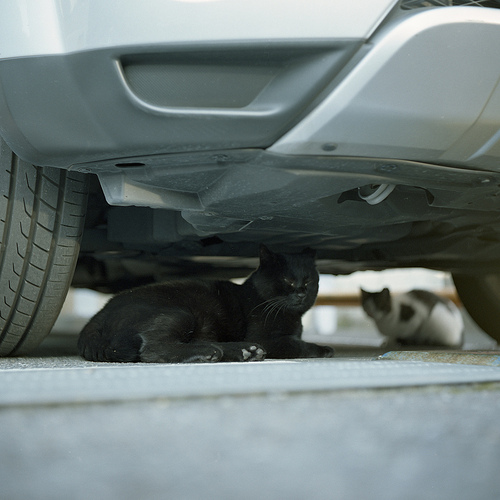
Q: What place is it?
A: It is a pavement.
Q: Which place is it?
A: It is a pavement.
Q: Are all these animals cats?
A: Yes, all the animals are cats.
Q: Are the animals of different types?
A: No, all the animals are cats.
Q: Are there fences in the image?
A: No, there are no fences.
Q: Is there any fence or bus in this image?
A: No, there are no fences or buses.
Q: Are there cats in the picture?
A: Yes, there is a cat.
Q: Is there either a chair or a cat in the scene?
A: Yes, there is a cat.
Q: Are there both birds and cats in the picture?
A: No, there is a cat but no birds.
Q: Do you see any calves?
A: No, there are no calves.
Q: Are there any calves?
A: No, there are no calves.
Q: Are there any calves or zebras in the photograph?
A: No, there are no calves or zebras.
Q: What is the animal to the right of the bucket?
A: The animal is a cat.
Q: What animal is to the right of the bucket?
A: The animal is a cat.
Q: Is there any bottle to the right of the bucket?
A: No, there is a cat to the right of the bucket.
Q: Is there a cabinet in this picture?
A: No, there are no cabinets.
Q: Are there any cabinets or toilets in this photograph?
A: No, there are no cabinets or toilets.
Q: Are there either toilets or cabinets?
A: No, there are no cabinets or toilets.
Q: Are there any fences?
A: No, there are no fences.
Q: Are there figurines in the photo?
A: No, there are no figurines.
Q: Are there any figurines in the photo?
A: No, there are no figurines.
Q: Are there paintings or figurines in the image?
A: No, there are no figurines or paintings.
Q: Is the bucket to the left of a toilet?
A: No, the bucket is to the left of the cat.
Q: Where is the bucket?
A: The bucket is on the ground.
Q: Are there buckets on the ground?
A: Yes, there is a bucket on the ground.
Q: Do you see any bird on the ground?
A: No, there is a bucket on the ground.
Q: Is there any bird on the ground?
A: No, there is a bucket on the ground.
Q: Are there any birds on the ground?
A: No, there is a bucket on the ground.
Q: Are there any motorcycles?
A: No, there are no motorcycles.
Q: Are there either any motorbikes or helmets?
A: No, there are no motorbikes or helmets.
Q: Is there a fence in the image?
A: No, there are no fences.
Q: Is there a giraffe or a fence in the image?
A: No, there are no fences or giraffes.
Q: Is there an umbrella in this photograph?
A: No, there are no umbrellas.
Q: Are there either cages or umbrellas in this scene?
A: No, there are no umbrellas or cages.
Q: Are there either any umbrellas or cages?
A: No, there are no umbrellas or cages.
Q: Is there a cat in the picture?
A: Yes, there are cats.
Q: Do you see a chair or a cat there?
A: Yes, there are cats.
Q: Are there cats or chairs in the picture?
A: Yes, there are cats.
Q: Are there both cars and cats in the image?
A: Yes, there are both cats and a car.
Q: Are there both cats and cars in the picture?
A: Yes, there are both cats and a car.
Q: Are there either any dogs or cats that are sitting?
A: Yes, the cats are sitting.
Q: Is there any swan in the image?
A: No, there are no swans.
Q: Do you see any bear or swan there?
A: No, there are no swans or bears.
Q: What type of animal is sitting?
A: The animal is cats.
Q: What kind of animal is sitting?
A: The animal is cats.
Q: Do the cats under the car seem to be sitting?
A: Yes, the cats are sitting.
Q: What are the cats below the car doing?
A: The cats are sitting.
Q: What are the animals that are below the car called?
A: The animals are cats.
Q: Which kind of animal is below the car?
A: The animals are cats.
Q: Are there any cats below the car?
A: Yes, there are cats below the car.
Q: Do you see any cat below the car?
A: Yes, there are cats below the car.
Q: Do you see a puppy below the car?
A: No, there are cats below the car.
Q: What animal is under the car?
A: The cats are under the car.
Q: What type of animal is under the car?
A: The animals are cats.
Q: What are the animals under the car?
A: The animals are cats.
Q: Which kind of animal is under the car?
A: The animals are cats.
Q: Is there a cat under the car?
A: Yes, there are cats under the car.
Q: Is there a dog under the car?
A: No, there are cats under the car.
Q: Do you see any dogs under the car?
A: No, there are cats under the car.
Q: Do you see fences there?
A: No, there are no fences.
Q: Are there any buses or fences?
A: No, there are no fences or buses.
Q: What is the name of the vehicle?
A: The vehicle is a car.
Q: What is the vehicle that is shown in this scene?
A: The vehicle is a car.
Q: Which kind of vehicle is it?
A: The vehicle is a car.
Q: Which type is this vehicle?
A: That is a car.